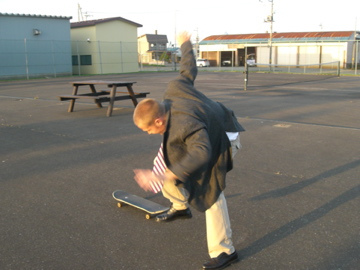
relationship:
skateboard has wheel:
[110, 188, 171, 221] [117, 202, 123, 209]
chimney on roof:
[154, 30, 157, 36] [138, 33, 169, 45]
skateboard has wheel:
[110, 188, 171, 221] [145, 212, 151, 221]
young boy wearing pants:
[132, 30, 246, 269] [161, 133, 242, 259]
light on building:
[31, 27, 40, 37] [1, 15, 74, 79]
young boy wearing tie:
[132, 30, 246, 269] [150, 140, 169, 194]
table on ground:
[59, 79, 151, 119] [1, 71, 360, 269]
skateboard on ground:
[110, 188, 171, 221] [1, 71, 360, 269]